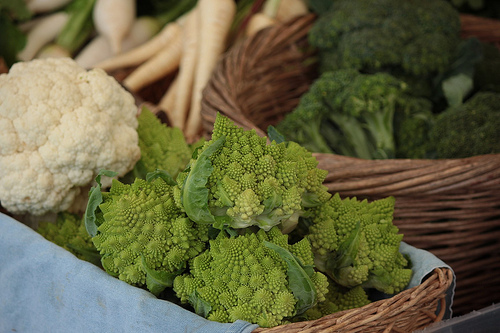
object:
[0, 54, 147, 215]
cauliflower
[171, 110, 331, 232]
stuff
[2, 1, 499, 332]
two baskets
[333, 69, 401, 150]
food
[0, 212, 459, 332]
cloth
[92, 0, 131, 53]
many different items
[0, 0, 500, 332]
photo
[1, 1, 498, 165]
background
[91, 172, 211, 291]
brussel sprouts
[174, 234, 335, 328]
vegetables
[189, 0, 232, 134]
ears of corn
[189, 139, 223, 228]
leaf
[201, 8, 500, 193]
basket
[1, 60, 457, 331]
basket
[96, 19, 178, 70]
rutabega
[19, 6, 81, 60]
parsnips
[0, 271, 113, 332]
side of basket